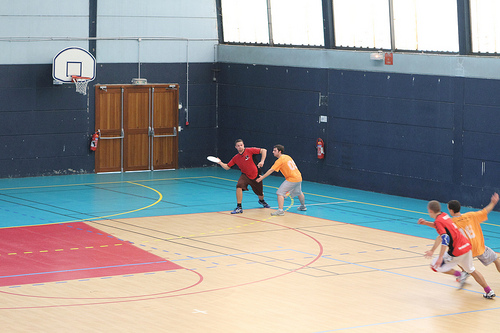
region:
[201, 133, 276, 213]
person playing frisbee in a building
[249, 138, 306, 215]
person playing frisbee in a building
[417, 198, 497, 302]
person playing frisbee in a building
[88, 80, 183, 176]
large brown door in a building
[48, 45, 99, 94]
back board and basketball hoop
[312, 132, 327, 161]
red fire extinguisher on the wall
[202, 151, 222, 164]
white frisbee in someones hand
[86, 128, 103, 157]
red fire extinguisher on the wall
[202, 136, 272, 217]
person wearing some brown shorts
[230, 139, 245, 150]
head of a person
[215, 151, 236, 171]
arm of a person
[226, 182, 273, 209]
legs of a person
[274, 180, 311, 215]
legs of a person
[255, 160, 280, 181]
arm of a person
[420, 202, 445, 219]
head of a person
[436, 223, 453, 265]
arm of a person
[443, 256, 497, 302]
legs of a person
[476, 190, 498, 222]
arm of a person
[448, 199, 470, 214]
head of a person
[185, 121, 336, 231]
the boys are playing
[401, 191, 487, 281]
the boys are playing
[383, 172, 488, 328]
the boys are playing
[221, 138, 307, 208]
boys are wearing jersey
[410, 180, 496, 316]
boys are wearing jersey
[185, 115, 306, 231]
boys are wearing jersey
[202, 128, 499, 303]
four players on the court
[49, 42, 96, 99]
basketball hoop hanging on the wall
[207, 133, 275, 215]
man holding a white frisbee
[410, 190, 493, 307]
player running on the court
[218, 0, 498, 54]
a row of windows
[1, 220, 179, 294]
red paint on the court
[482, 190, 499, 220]
arm in the air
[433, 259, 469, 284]
foot lifted off the ground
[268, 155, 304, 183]
yellow and white shirt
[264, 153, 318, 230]
A person playing basketball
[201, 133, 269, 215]
A person playing basketball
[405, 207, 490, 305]
A person playing basketball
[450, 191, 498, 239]
A person playing basketball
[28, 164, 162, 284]
A buscket ball court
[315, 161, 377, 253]
A buscket ball court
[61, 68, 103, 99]
A buscket ball net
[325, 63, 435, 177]
A buscket ball blue wall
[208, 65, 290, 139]
A buscket ball blue wall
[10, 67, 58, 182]
A buscket ball blue wall